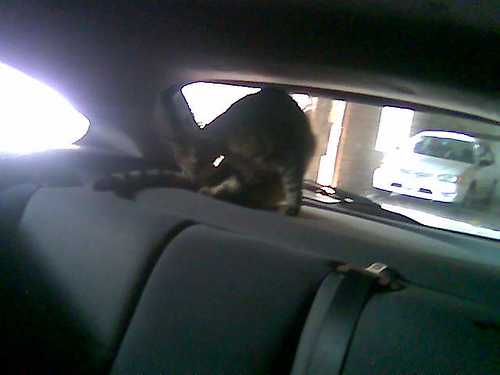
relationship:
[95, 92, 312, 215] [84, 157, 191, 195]
cat has tail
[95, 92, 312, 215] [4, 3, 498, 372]
cat on car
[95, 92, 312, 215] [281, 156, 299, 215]
cat has stripes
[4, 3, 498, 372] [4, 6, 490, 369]
car dark inside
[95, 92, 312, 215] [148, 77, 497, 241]
cat sits in back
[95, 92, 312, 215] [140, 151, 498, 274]
cat on back seat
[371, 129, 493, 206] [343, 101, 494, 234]
car in background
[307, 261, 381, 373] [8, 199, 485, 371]
belt on back seat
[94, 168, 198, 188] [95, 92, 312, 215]
tail of cat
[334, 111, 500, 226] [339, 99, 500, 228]
garage in back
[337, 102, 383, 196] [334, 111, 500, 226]
brick wall near garage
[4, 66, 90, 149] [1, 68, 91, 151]
sun through window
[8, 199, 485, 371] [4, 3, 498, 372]
seat of car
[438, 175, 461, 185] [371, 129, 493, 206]
headlights of car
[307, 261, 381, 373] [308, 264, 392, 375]
seatbelt ready to be used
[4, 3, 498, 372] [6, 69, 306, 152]
vehicle with natural light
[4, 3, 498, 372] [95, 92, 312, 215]
car showing windows and cat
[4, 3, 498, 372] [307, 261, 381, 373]
car showing seat belt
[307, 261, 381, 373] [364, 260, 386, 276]
belt with metal buckle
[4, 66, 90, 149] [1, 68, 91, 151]
sun entering side window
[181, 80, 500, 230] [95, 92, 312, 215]
window visible behind cat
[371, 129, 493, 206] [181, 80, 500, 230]
car visible through window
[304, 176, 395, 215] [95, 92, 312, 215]
wiper obstructed by cat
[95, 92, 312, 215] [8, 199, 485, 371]
cat touching seat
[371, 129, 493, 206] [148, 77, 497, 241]
car parked in back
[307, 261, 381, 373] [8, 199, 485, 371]
seatbelt on back seat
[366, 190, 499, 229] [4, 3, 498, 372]
ground behind car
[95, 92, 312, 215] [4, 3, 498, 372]
cat in car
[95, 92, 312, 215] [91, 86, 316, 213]
cat cleaning itself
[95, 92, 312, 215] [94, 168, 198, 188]
cat has a tail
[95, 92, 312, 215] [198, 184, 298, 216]
cat has paws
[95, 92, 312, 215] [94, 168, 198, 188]
cat's long tail